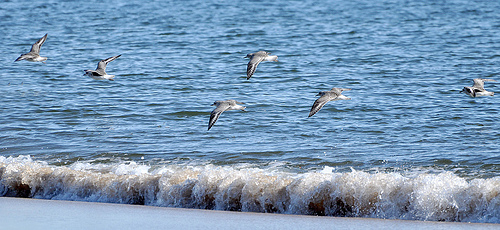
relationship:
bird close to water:
[447, 74, 498, 106] [2, 2, 497, 189]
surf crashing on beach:
[0, 153, 499, 222] [3, 171, 427, 228]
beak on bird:
[458, 89, 463, 94] [447, 74, 498, 106]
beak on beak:
[311, 92, 319, 97] [81, 68, 88, 73]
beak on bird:
[241, 55, 248, 60] [241, 46, 277, 82]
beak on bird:
[209, 102, 214, 108] [203, 95, 248, 136]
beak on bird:
[81, 68, 88, 73] [82, 52, 128, 85]